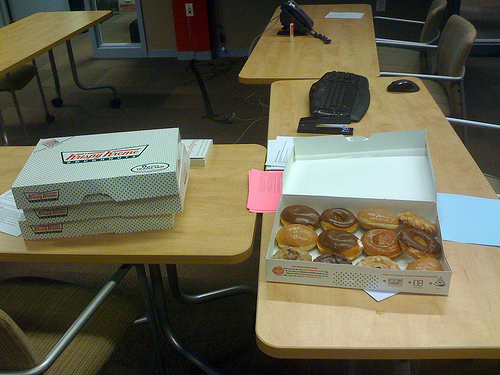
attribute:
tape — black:
[188, 58, 233, 127]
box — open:
[267, 130, 452, 295]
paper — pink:
[247, 168, 285, 214]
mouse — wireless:
[386, 80, 420, 93]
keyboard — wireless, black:
[309, 71, 370, 121]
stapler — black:
[296, 115, 354, 138]